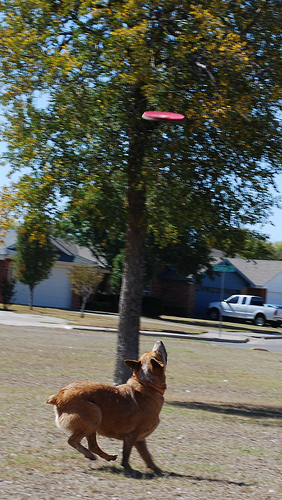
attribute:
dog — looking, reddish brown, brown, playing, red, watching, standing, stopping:
[46, 339, 168, 477]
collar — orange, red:
[130, 372, 166, 396]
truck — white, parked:
[203, 293, 281, 327]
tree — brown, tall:
[2, 2, 281, 388]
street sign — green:
[210, 263, 237, 274]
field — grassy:
[2, 324, 279, 499]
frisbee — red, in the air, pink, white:
[139, 109, 188, 125]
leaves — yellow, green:
[0, 0, 281, 264]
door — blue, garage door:
[194, 290, 240, 323]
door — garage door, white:
[10, 266, 73, 309]